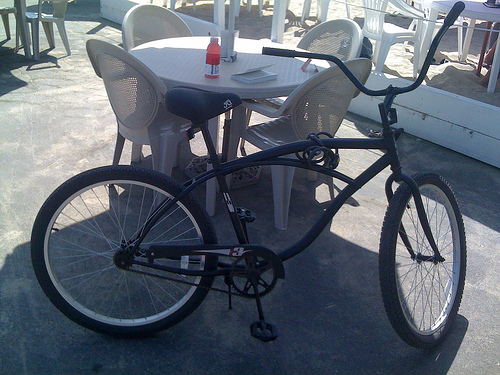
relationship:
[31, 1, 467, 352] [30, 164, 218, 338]
bike has a wheel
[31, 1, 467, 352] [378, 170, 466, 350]
bike has a wheel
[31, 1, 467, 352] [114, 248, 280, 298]
bike has a chain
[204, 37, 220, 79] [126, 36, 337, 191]
bottle on table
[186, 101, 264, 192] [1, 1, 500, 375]
stand on ground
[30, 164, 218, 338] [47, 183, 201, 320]
wheel has wiring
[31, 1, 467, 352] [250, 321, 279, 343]
bike has a pedal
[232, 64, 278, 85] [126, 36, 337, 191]
book on table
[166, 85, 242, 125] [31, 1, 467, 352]
seat on bike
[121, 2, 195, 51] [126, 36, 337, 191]
chair under table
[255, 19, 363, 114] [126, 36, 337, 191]
chair under table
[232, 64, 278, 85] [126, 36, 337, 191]
book sitting on table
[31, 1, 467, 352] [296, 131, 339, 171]
bike has a lock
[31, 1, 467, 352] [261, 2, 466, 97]
bike has handle bars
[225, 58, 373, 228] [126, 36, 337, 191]
chair under table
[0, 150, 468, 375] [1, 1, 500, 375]
shadow on ground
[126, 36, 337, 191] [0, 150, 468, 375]
table has a shadow